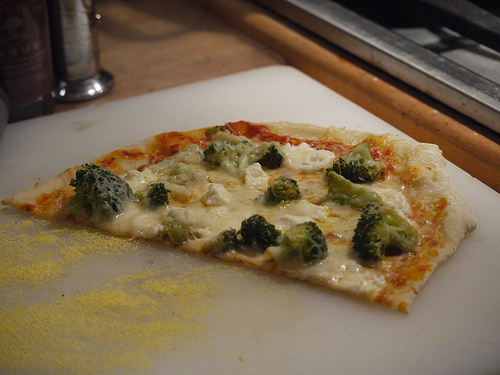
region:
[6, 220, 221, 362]
yellow seasonings on plate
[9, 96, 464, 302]
half of a pizza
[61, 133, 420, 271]
broccoli pieces on pizza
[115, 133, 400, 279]
cheese topping of pizza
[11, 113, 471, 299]
crust of the pizza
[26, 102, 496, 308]
half a pizza topped with broccoli and cheese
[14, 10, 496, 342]
table that pizza is on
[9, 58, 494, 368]
white plate that pizza is on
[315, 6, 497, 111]
metal bar next to pizza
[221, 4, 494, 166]
wood bar next to pizza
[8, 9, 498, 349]
half of a vegetarian pizza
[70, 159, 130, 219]
cooked broccoli floret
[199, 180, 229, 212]
lump of unmelted feta cheese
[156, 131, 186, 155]
tomato sauce on a crust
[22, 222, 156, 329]
yellow cornmeal scattered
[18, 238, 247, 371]
yellow corn meal on a cutting board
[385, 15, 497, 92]
edge of a stove top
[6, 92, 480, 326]
half of a pizza on a cutting board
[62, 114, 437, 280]
broccoli and cheese pizza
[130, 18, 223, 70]
faded wood table top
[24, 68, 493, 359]
pizza on a table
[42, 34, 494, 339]
half a pizza on a table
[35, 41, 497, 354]
a cooked pizza on a table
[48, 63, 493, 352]
a baked pizza on a table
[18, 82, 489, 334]
half a baked pizza on a table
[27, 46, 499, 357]
half a cooked pizza on a table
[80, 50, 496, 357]
pizza with sauce and cheese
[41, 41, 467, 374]
a pizza with brocolli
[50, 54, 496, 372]
pizza with green brocolli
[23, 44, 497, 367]
pizza with cheese and brocolli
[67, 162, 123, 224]
broccoli on the pizza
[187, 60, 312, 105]
white board that pizza is on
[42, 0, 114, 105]
silver salt shaker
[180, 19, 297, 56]
part of wooden table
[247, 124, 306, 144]
pizza sauce on the pizza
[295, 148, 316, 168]
cheese on the pizza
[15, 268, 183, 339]
seasoning on the white board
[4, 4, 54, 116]
silver pepper shaker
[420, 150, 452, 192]
crust of the pizza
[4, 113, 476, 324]
a piece of pizza on a cutting board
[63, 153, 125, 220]
brocolli is one of the toppings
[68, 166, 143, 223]
brocolli is green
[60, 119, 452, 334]
the sauce was lightly covering the pizza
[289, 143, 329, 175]
the cheese is mutzarella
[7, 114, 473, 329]
it is a thin crust pizza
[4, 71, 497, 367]
there is a cutting board under the pizza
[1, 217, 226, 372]
a yellow substance is on the cutting board that looks like corn flour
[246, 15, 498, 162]
the table has a brown raised edge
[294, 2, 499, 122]
a metal edging on the stove